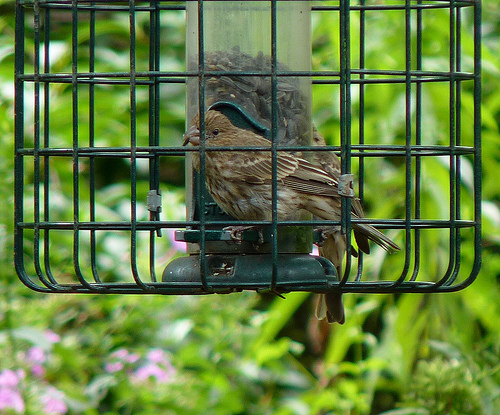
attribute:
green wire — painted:
[340, 0, 357, 178]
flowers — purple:
[3, 326, 73, 413]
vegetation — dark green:
[166, 321, 321, 397]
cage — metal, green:
[9, 9, 473, 299]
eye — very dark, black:
[211, 127, 221, 137]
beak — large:
[177, 124, 199, 148]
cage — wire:
[21, 13, 170, 293]